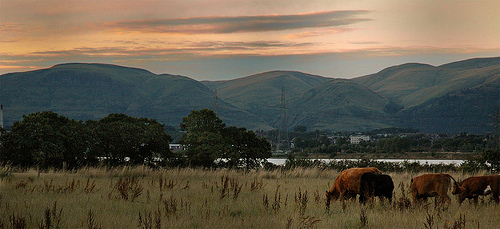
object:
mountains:
[0, 62, 266, 134]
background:
[0, 1, 500, 154]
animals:
[325, 167, 381, 213]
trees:
[0, 110, 103, 167]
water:
[94, 153, 498, 167]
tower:
[275, 82, 289, 152]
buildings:
[350, 132, 370, 144]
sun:
[1, 37, 41, 57]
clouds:
[124, 9, 361, 35]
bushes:
[258, 159, 278, 171]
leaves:
[51, 128, 53, 129]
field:
[0, 162, 495, 228]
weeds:
[135, 205, 166, 229]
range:
[0, 57, 500, 135]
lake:
[145, 156, 499, 167]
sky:
[1, 0, 497, 81]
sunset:
[0, 1, 66, 69]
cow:
[450, 174, 499, 206]